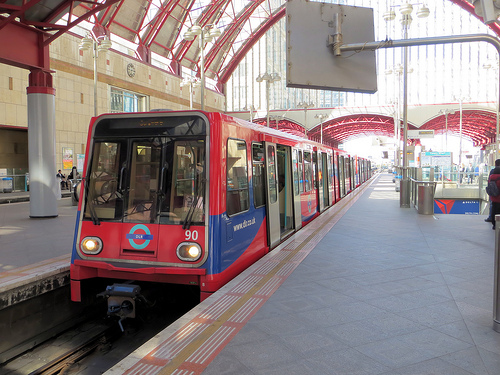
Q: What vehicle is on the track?
A: Train.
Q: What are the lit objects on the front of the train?
A: Headlights.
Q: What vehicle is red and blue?
A: The train.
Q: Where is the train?
A: On the tracks.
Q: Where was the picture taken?
A: At a train station.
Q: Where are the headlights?
A: On the front of the train.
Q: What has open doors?
A: The train.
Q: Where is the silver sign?
A: Next to the train.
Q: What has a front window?
A: The train.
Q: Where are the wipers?
A: On the front of the train.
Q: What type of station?
A: Train.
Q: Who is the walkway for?
A: Pedestrian.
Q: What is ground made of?
A: Concrete.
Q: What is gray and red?
A: Column.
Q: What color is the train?
A: Red.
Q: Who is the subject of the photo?
A: The train.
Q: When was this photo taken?
A: During the day.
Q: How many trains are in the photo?
A: One.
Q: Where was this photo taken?
A: In a station.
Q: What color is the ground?
A: Gray.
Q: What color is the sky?
A: White.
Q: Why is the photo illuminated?
A: Sunlight.